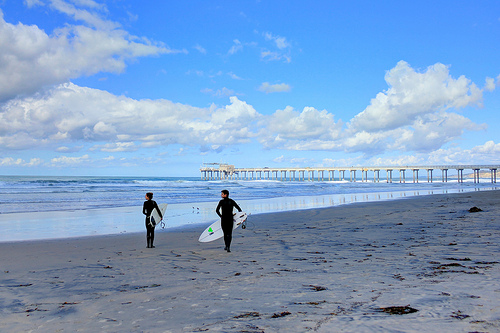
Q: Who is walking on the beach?
A: The surfers.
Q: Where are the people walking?
A: On the beach.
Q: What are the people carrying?
A: Surfboards.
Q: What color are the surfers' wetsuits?
A: Black.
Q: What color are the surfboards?
A: White.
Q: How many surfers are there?
A: Two.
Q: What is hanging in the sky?
A: Clouds.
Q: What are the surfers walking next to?
A: The ocean.